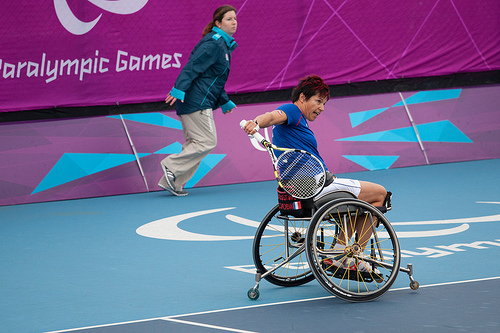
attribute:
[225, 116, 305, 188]
shirt — t shirt, blue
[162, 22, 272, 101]
jacket — blue